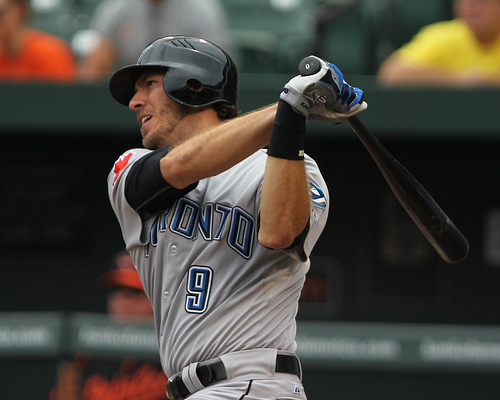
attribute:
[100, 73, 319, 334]
man — swinging, white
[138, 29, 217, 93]
helmet — black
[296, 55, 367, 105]
glove — blue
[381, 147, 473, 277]
bat — black